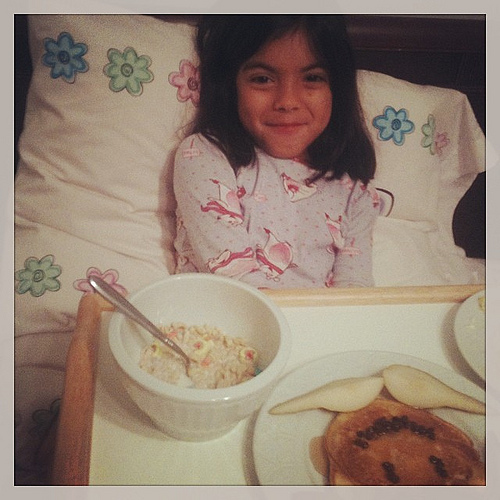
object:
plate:
[453, 290, 485, 382]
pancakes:
[323, 397, 486, 486]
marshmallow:
[242, 343, 257, 363]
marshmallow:
[192, 338, 207, 352]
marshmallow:
[198, 354, 214, 368]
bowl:
[106, 271, 292, 444]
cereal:
[135, 319, 263, 390]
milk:
[136, 321, 258, 388]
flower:
[39, 31, 89, 85]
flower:
[102, 46, 154, 97]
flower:
[168, 58, 202, 108]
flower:
[15, 254, 62, 298]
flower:
[73, 266, 129, 298]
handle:
[88, 275, 191, 364]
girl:
[170, 14, 381, 293]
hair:
[175, 14, 376, 187]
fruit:
[194, 339, 214, 367]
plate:
[250, 349, 485, 486]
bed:
[12, 13, 485, 484]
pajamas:
[172, 128, 381, 289]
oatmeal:
[138, 319, 260, 389]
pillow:
[14, 13, 485, 286]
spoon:
[88, 274, 199, 377]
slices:
[267, 364, 486, 487]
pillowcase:
[14, 13, 487, 485]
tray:
[49, 283, 487, 488]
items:
[48, 275, 486, 487]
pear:
[266, 363, 485, 415]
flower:
[369, 104, 416, 148]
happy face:
[354, 413, 449, 487]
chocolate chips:
[352, 414, 436, 449]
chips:
[267, 364, 484, 416]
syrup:
[309, 432, 329, 476]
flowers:
[421, 113, 450, 157]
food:
[107, 319, 485, 486]